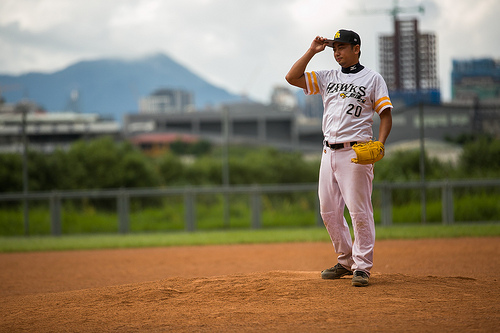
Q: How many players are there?
A: One.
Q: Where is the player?
A: In the field.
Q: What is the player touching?
A: His hat.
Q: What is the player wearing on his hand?
A: A baseball glove.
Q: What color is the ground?
A: Brown.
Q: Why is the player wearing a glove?
A: To catch balls.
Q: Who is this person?
A: A baseball player.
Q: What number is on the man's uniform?
A: 20.